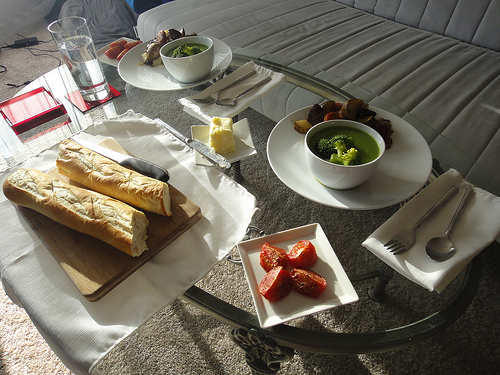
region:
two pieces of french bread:
[22, 120, 200, 287]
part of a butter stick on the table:
[203, 98, 269, 178]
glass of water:
[49, 4, 120, 131]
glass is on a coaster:
[47, 82, 132, 117]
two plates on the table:
[157, 12, 412, 238]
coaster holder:
[5, 74, 72, 137]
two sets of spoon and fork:
[213, 46, 486, 262]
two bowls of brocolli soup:
[190, 26, 379, 208]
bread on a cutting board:
[37, 129, 249, 302]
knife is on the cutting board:
[100, 131, 166, 185]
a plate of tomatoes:
[222, 227, 372, 329]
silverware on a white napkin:
[360, 162, 497, 301]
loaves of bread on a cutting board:
[5, 116, 190, 301]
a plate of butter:
[162, 87, 264, 200]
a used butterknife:
[173, 129, 229, 173]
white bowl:
[149, 30, 229, 82]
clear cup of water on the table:
[39, 15, 134, 121]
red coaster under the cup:
[69, 75, 116, 128]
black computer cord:
[7, 21, 48, 65]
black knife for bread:
[72, 135, 194, 192]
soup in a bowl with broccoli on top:
[303, 111, 387, 195]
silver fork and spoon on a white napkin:
[362, 163, 499, 294]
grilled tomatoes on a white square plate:
[221, 213, 362, 340]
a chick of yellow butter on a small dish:
[186, 106, 260, 169]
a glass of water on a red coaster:
[41, 10, 126, 112]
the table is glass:
[10, 32, 497, 374]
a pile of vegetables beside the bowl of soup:
[289, 90, 396, 193]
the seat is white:
[131, 0, 497, 224]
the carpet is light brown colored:
[6, 20, 498, 374]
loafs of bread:
[26, 168, 158, 233]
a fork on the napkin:
[379, 221, 401, 263]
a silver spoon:
[432, 224, 459, 271]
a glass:
[60, 41, 117, 94]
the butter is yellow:
[209, 115, 246, 150]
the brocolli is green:
[307, 123, 364, 168]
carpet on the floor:
[165, 329, 220, 364]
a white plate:
[287, 149, 305, 180]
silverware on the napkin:
[205, 80, 244, 116]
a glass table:
[246, 179, 294, 214]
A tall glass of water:
[37, 16, 114, 103]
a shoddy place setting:
[403, 169, 465, 289]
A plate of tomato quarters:
[236, 225, 353, 320]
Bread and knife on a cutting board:
[7, 145, 182, 265]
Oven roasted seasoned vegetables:
[290, 90, 400, 145]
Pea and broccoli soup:
[306, 120, 383, 174]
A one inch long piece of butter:
[185, 115, 262, 163]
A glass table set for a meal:
[11, 22, 484, 359]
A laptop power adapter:
[4, 30, 41, 53]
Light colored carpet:
[157, 320, 214, 363]